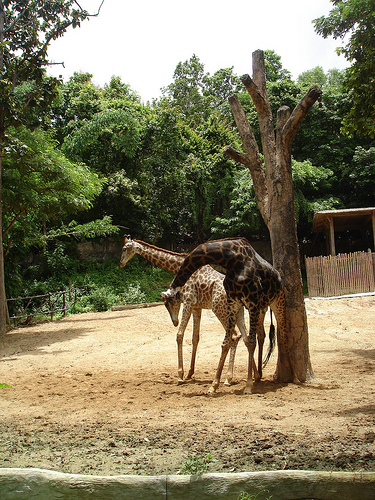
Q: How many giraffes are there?
A: 2.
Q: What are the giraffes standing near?
A: Tree.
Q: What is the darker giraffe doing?
A: Bending down.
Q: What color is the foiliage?
A: Green.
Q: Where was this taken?
A: Zoo.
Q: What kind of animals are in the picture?
A: Giraffes.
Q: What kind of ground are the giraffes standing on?
A: Sand.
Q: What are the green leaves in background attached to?
A: Trees.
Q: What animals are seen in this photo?
A: Giraffes.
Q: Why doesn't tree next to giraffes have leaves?
A: Branches have been cut.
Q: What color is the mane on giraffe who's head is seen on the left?
A: Light brown.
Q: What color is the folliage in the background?
A: Green.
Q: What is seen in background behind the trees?
A: Sky.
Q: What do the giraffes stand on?
A: Hooves.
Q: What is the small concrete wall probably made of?
A: Concrete.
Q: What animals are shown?
A: Giraffes.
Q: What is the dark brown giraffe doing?
A: Looking.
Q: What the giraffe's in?
A: Pen.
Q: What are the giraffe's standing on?
A: Dirt.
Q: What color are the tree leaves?
A: Green.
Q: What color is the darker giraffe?
A: Brown and tan.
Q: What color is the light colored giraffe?
A: Tan and brown.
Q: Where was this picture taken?
A: Zoo.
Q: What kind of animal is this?
A: Giraffe.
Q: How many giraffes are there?
A: Two.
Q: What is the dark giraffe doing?
A: Scratching his rump.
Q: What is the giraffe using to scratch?
A: Tree trunk.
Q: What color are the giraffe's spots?
A: Brown.